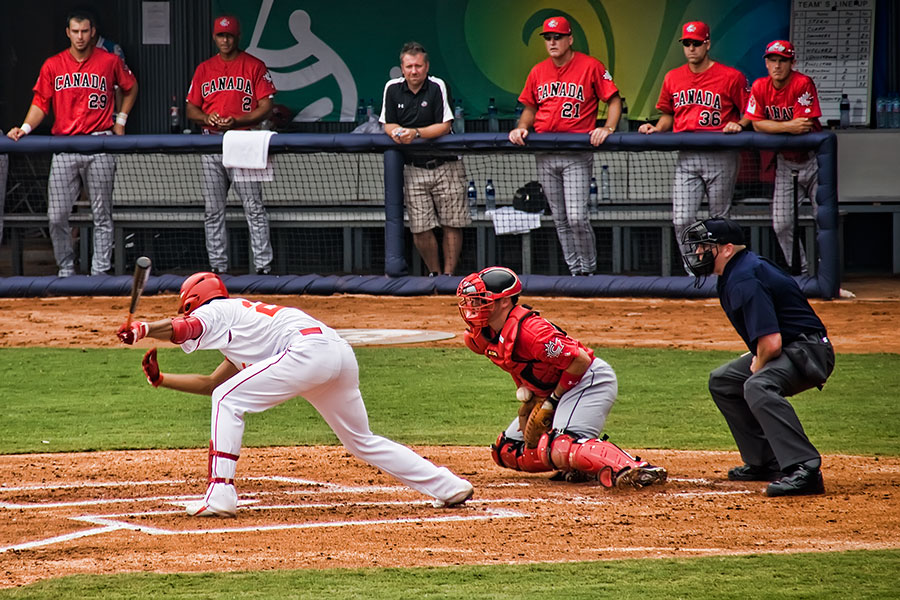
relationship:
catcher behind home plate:
[448, 250, 672, 498] [158, 487, 267, 514]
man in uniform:
[21, 20, 138, 278] [26, 48, 132, 262]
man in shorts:
[378, 50, 481, 274] [388, 157, 471, 235]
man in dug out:
[378, 50, 481, 274] [17, 127, 858, 305]